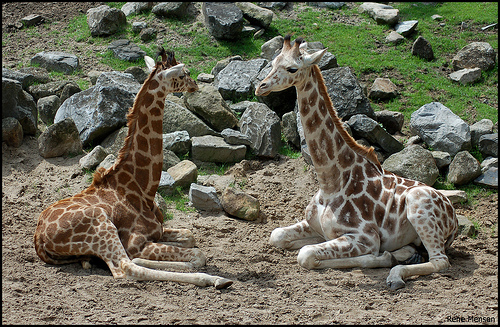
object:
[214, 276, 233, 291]
hoof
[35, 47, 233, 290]
giraffe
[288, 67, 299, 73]
eye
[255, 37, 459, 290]
giraffe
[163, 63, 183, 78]
ear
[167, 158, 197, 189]
rock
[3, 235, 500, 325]
ground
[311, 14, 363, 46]
grass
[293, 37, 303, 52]
horn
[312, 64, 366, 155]
mane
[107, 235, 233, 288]
leg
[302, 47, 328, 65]
ear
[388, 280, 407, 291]
hoof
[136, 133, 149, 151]
spot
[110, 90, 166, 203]
neck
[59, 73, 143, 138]
rock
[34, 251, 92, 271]
tail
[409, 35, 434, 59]
rock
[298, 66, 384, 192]
neck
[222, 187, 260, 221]
rock